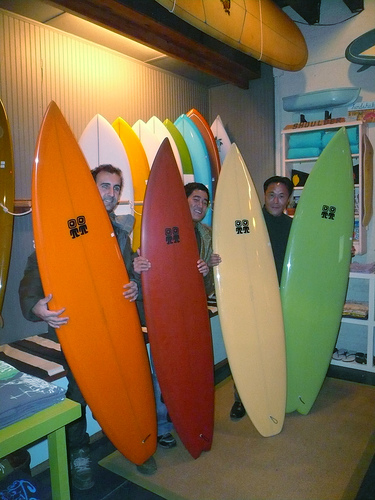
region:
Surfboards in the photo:
[40, 186, 273, 353]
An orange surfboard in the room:
[90, 314, 153, 415]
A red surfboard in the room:
[167, 300, 199, 405]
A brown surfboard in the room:
[225, 285, 272, 379]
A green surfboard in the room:
[302, 240, 335, 351]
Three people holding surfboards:
[79, 156, 285, 304]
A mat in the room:
[240, 451, 342, 492]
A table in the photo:
[34, 405, 68, 454]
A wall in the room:
[310, 23, 341, 79]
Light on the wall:
[92, 37, 172, 109]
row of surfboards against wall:
[75, 110, 232, 228]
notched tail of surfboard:
[187, 439, 215, 456]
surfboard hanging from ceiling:
[158, 0, 308, 70]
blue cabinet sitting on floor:
[328, 265, 373, 372]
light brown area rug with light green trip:
[99, 370, 373, 499]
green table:
[0, 398, 81, 499]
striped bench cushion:
[0, 290, 217, 379]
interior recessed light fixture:
[46, 12, 166, 63]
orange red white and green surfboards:
[33, 99, 355, 463]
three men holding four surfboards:
[22, 100, 357, 465]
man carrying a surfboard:
[120, 127, 235, 456]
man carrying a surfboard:
[206, 137, 290, 469]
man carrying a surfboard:
[270, 129, 345, 499]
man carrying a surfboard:
[15, 115, 162, 486]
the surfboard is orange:
[22, 147, 114, 495]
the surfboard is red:
[133, 124, 191, 484]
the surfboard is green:
[301, 143, 350, 491]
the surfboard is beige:
[210, 153, 320, 481]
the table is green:
[13, 377, 95, 495]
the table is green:
[41, 396, 105, 487]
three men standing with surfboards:
[46, 152, 307, 280]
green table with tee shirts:
[24, 408, 73, 498]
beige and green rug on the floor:
[306, 433, 369, 499]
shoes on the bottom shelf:
[338, 343, 365, 366]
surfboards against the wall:
[85, 107, 245, 160]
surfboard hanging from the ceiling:
[152, 5, 327, 69]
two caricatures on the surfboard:
[64, 205, 90, 247]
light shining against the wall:
[39, 8, 155, 81]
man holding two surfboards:
[211, 170, 372, 295]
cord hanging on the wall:
[286, 13, 364, 32]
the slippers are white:
[331, 337, 360, 371]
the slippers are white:
[322, 336, 374, 381]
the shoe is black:
[214, 390, 259, 424]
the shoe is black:
[220, 393, 252, 449]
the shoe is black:
[229, 392, 246, 440]